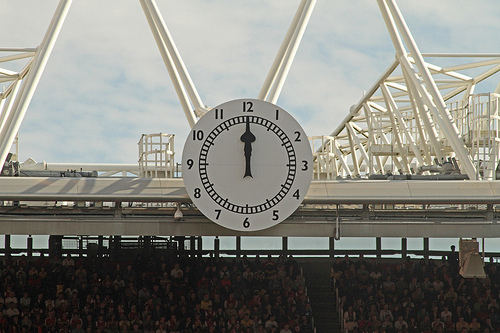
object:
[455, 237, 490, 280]
light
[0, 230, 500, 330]
stadium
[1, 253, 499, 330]
stands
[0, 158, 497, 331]
stadium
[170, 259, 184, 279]
person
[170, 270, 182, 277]
shirt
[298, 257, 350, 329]
stairs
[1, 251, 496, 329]
seating area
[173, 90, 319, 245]
clock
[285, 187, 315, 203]
number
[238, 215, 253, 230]
number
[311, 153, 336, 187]
ground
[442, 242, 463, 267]
person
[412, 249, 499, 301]
man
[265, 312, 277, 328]
patron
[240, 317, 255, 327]
patron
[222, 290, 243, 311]
patron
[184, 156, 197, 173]
number 9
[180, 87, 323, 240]
clock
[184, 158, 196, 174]
9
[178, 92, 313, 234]
clock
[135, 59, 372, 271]
clock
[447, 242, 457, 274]
person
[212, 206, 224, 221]
number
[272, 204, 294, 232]
number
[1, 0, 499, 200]
metal structure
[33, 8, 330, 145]
sky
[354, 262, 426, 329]
people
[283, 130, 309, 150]
number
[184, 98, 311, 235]
clock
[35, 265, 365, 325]
people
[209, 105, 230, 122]
11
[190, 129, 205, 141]
number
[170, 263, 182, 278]
person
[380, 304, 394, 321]
person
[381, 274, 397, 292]
person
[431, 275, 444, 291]
person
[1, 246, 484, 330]
stands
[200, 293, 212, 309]
person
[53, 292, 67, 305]
person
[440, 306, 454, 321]
person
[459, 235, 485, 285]
pole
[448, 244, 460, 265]
man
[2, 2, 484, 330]
stadium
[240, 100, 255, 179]
12:00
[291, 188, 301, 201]
number 4